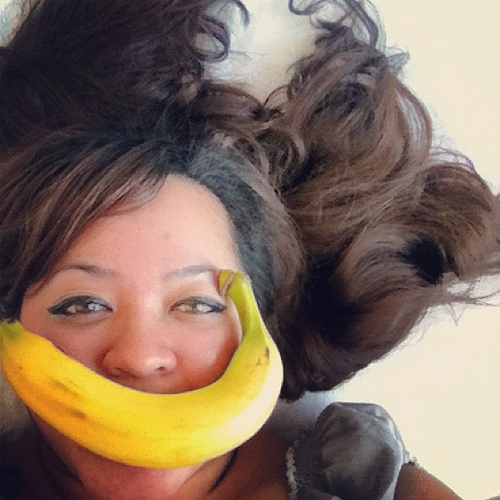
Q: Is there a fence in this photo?
A: No, there are no fences.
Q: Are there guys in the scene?
A: No, there are no guys.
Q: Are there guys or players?
A: No, there are no guys or players.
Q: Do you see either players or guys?
A: No, there are no guys or players.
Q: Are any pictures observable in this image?
A: No, there are no pictures.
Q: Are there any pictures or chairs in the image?
A: No, there are no pictures or chairs.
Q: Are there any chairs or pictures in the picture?
A: No, there are no pictures or chairs.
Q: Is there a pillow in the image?
A: No, there are no pillows.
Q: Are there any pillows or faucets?
A: No, there are no pillows or faucets.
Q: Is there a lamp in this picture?
A: No, there are no lamps.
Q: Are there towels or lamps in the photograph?
A: No, there are no lamps or towels.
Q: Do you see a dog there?
A: No, there are no dogs.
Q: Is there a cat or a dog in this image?
A: No, there are no dogs or cats.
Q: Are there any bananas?
A: Yes, there is a banana.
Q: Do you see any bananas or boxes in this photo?
A: Yes, there is a banana.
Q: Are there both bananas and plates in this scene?
A: No, there is a banana but no plates.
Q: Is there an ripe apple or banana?
A: Yes, there is a ripe banana.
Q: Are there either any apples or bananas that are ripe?
A: Yes, the banana is ripe.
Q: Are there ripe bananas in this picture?
A: Yes, there is a ripe banana.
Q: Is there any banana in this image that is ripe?
A: Yes, there is a banana that is ripe.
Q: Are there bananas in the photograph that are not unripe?
A: Yes, there is an ripe banana.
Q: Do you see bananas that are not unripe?
A: Yes, there is an ripe banana.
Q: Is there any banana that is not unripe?
A: Yes, there is an ripe banana.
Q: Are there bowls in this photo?
A: No, there are no bowls.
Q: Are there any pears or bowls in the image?
A: No, there are no bowls or pears.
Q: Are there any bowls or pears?
A: No, there are no bowls or pears.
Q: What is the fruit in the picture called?
A: The fruit is a banana.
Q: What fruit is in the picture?
A: The fruit is a banana.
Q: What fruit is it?
A: The fruit is a banana.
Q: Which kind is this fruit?
A: This is a banana.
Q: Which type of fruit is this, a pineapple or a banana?
A: This is a banana.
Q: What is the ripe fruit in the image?
A: The fruit is a banana.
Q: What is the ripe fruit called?
A: The fruit is a banana.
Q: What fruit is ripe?
A: The fruit is a banana.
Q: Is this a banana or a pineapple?
A: This is a banana.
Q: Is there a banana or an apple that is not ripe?
A: No, there is a banana but it is ripe.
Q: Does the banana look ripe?
A: Yes, the banana is ripe.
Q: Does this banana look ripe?
A: Yes, the banana is ripe.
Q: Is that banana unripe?
A: No, the banana is ripe.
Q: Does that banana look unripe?
A: No, the banana is ripe.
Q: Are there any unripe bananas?
A: No, there is a banana but it is ripe.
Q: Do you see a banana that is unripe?
A: No, there is a banana but it is ripe.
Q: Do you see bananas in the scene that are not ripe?
A: No, there is a banana but it is ripe.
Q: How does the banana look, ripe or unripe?
A: The banana is ripe.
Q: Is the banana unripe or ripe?
A: The banana is ripe.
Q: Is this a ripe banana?
A: Yes, this is a ripe banana.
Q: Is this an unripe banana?
A: No, this is a ripe banana.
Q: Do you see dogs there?
A: No, there are no dogs.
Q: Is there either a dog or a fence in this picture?
A: No, there are no dogs or fences.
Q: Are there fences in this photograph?
A: No, there are no fences.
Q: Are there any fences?
A: No, there are no fences.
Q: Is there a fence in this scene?
A: No, there are no fences.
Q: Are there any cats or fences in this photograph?
A: No, there are no fences or cats.